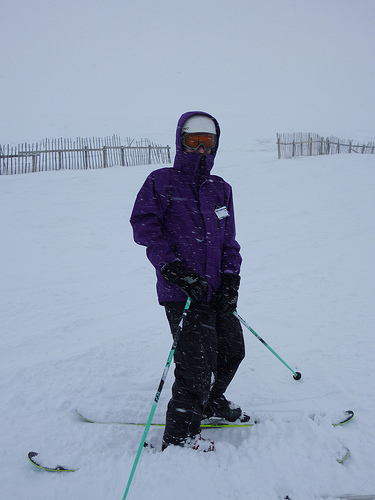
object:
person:
[129, 110, 246, 453]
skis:
[27, 407, 356, 473]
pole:
[122, 297, 193, 500]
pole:
[233, 311, 302, 380]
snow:
[0, 153, 372, 499]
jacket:
[129, 111, 242, 306]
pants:
[164, 302, 245, 436]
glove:
[214, 272, 242, 320]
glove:
[161, 258, 208, 304]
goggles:
[180, 132, 218, 152]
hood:
[174, 111, 221, 174]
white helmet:
[181, 115, 217, 135]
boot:
[162, 399, 215, 452]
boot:
[203, 381, 242, 423]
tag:
[214, 206, 231, 221]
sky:
[1, 0, 368, 148]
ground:
[0, 155, 374, 500]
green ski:
[200, 418, 255, 428]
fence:
[276, 132, 375, 160]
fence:
[0, 134, 171, 175]